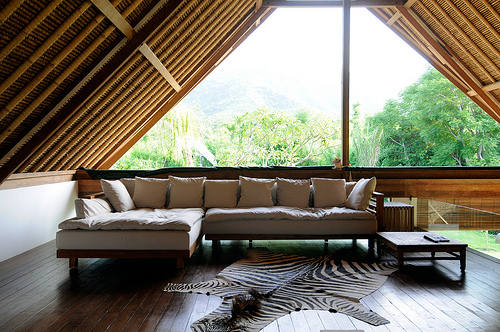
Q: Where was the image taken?
A: It was taken at the living room.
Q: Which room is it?
A: It is a living room.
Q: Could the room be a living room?
A: Yes, it is a living room.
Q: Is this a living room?
A: Yes, it is a living room.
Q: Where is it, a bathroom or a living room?
A: It is a living room.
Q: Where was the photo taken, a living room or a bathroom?
A: It was taken at a living room.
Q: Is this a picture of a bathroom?
A: No, the picture is showing a living room.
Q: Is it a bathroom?
A: No, it is a living room.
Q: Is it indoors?
A: Yes, it is indoors.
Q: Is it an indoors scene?
A: Yes, it is indoors.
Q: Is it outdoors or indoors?
A: It is indoors.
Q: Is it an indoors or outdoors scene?
A: It is indoors.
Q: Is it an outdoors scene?
A: No, it is indoors.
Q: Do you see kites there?
A: No, there are no kites.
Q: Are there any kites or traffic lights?
A: No, there are no kites or traffic lights.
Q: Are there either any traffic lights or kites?
A: No, there are no kites or traffic lights.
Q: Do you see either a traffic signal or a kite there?
A: No, there are no kites or traffic lights.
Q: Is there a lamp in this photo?
A: No, there are no lamps.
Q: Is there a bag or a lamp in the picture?
A: No, there are no lamps or bags.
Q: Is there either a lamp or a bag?
A: No, there are no lamps or bags.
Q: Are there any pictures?
A: No, there are no pictures.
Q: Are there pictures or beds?
A: No, there are no pictures or beds.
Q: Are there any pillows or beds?
A: Yes, there is a pillow.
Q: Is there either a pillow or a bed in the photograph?
A: Yes, there is a pillow.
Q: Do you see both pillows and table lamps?
A: No, there is a pillow but no table lamps.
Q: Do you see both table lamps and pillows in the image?
A: No, there is a pillow but no table lamps.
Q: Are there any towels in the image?
A: No, there are no towels.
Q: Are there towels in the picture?
A: No, there are no towels.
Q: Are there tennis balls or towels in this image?
A: No, there are no towels or tennis balls.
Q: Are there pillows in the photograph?
A: Yes, there is a pillow.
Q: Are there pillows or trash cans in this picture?
A: Yes, there is a pillow.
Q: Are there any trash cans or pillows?
A: Yes, there is a pillow.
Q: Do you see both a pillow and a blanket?
A: No, there is a pillow but no blankets.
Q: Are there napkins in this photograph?
A: No, there are no napkins.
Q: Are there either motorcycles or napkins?
A: No, there are no napkins or motorcycles.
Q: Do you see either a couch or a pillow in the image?
A: Yes, there is a pillow.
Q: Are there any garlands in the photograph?
A: No, there are no garlands.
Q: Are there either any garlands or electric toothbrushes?
A: No, there are no garlands or electric toothbrushes.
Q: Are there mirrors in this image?
A: No, there are no mirrors.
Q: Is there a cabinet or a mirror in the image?
A: No, there are no mirrors or cabinets.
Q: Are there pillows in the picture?
A: Yes, there is a pillow.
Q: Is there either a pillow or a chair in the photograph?
A: Yes, there is a pillow.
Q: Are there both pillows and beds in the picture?
A: No, there is a pillow but no beds.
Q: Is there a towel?
A: No, there are no towels.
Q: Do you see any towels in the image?
A: No, there are no towels.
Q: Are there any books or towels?
A: No, there are no towels or books.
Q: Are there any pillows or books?
A: Yes, there is a pillow.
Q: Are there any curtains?
A: No, there are no curtains.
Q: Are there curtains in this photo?
A: No, there are no curtains.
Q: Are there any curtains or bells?
A: No, there are no curtains or bells.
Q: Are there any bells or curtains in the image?
A: No, there are no curtains or bells.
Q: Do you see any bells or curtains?
A: No, there are no curtains or bells.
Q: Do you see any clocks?
A: No, there are no clocks.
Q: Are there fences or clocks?
A: No, there are no clocks or fences.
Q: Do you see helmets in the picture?
A: No, there are no helmets.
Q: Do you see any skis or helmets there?
A: No, there are no helmets or skis.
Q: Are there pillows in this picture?
A: Yes, there is a pillow.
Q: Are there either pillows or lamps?
A: Yes, there is a pillow.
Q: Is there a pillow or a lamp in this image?
A: Yes, there is a pillow.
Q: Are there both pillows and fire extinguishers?
A: No, there is a pillow but no fire extinguishers.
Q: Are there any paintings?
A: No, there are no paintings.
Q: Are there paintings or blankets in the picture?
A: No, there are no paintings or blankets.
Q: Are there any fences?
A: No, there are no fences.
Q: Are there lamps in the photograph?
A: No, there are no lamps.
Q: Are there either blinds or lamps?
A: No, there are no lamps or blinds.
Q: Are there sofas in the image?
A: Yes, there is a sofa.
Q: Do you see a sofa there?
A: Yes, there is a sofa.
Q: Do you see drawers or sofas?
A: Yes, there is a sofa.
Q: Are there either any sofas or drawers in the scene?
A: Yes, there is a sofa.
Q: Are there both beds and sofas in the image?
A: No, there is a sofa but no beds.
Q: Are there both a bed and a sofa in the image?
A: No, there is a sofa but no beds.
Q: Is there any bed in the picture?
A: No, there are no beds.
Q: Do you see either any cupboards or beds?
A: No, there are no beds or cupboards.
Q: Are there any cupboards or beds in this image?
A: No, there are no beds or cupboards.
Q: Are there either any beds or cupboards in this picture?
A: No, there are no beds or cupboards.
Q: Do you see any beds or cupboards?
A: No, there are no beds or cupboards.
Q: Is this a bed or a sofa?
A: This is a sofa.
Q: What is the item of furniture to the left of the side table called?
A: The piece of furniture is a sofa.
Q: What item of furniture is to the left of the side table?
A: The piece of furniture is a sofa.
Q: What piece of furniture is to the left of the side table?
A: The piece of furniture is a sofa.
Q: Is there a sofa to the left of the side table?
A: Yes, there is a sofa to the left of the side table.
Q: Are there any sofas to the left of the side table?
A: Yes, there is a sofa to the left of the side table.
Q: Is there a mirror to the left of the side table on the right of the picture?
A: No, there is a sofa to the left of the side table.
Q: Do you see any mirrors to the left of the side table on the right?
A: No, there is a sofa to the left of the side table.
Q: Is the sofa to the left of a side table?
A: Yes, the sofa is to the left of a side table.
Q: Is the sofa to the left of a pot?
A: No, the sofa is to the left of a side table.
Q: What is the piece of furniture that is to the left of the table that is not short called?
A: The piece of furniture is a sofa.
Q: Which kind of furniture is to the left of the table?
A: The piece of furniture is a sofa.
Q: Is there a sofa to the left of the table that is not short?
A: Yes, there is a sofa to the left of the table.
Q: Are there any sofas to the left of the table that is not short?
A: Yes, there is a sofa to the left of the table.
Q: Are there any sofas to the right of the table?
A: No, the sofa is to the left of the table.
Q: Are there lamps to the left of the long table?
A: No, there is a sofa to the left of the table.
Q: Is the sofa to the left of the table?
A: Yes, the sofa is to the left of the table.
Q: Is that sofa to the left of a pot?
A: No, the sofa is to the left of the table.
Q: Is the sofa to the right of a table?
A: No, the sofa is to the left of a table.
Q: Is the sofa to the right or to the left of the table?
A: The sofa is to the left of the table.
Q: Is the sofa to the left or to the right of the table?
A: The sofa is to the left of the table.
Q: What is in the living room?
A: The sofa is in the living room.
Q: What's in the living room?
A: The sofa is in the living room.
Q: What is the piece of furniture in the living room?
A: The piece of furniture is a sofa.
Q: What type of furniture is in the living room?
A: The piece of furniture is a sofa.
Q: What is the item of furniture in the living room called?
A: The piece of furniture is a sofa.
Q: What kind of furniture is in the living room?
A: The piece of furniture is a sofa.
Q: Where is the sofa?
A: The sofa is in the living room.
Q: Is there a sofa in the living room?
A: Yes, there is a sofa in the living room.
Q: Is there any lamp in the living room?
A: No, there is a sofa in the living room.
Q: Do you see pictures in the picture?
A: No, there are no pictures.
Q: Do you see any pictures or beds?
A: No, there are no pictures or beds.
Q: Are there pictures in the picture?
A: No, there are no pictures.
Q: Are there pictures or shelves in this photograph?
A: No, there are no pictures or shelves.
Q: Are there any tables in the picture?
A: Yes, there is a table.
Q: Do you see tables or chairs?
A: Yes, there is a table.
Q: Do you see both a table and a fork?
A: No, there is a table but no forks.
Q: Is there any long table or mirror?
A: Yes, there is a long table.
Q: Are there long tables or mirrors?
A: Yes, there is a long table.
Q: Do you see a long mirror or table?
A: Yes, there is a long table.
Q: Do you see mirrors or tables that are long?
A: Yes, the table is long.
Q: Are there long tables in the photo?
A: Yes, there is a long table.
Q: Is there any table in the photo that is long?
A: Yes, there is a table that is long.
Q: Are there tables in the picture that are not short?
A: Yes, there is a long table.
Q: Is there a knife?
A: No, there are no knives.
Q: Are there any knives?
A: No, there are no knives.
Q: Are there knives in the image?
A: No, there are no knives.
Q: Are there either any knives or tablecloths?
A: No, there are no knives or tablecloths.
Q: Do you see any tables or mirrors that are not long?
A: No, there is a table but it is long.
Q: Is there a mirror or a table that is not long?
A: No, there is a table but it is long.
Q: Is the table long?
A: Yes, the table is long.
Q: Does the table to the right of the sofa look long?
A: Yes, the table is long.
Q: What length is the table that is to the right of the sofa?
A: The table is long.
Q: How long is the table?
A: The table is long.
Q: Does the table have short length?
A: No, the table is long.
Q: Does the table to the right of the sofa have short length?
A: No, the table is long.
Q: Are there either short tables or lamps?
A: No, there is a table but it is long.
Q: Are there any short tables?
A: No, there is a table but it is long.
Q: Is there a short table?
A: No, there is a table but it is long.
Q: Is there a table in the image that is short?
A: No, there is a table but it is long.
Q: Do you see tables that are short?
A: No, there is a table but it is long.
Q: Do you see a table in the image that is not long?
A: No, there is a table but it is long.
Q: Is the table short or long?
A: The table is long.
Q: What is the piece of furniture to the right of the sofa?
A: The piece of furniture is a table.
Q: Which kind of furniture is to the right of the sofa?
A: The piece of furniture is a table.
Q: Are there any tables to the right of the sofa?
A: Yes, there is a table to the right of the sofa.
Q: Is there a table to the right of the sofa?
A: Yes, there is a table to the right of the sofa.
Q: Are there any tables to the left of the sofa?
A: No, the table is to the right of the sofa.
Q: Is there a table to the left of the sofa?
A: No, the table is to the right of the sofa.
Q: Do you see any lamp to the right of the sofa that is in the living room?
A: No, there is a table to the right of the sofa.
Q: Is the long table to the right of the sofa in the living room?
A: Yes, the table is to the right of the sofa.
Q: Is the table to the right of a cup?
A: No, the table is to the right of the sofa.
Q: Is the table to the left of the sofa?
A: No, the table is to the right of the sofa.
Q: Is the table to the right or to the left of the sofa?
A: The table is to the right of the sofa.